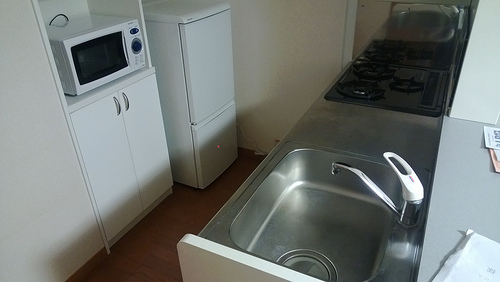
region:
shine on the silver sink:
[283, 158, 320, 189]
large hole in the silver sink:
[287, 243, 352, 275]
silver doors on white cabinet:
[95, 88, 143, 120]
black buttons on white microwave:
[113, 20, 153, 74]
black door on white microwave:
[62, 35, 150, 84]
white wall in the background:
[243, 24, 318, 91]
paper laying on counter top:
[468, 122, 497, 164]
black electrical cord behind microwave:
[47, 12, 96, 37]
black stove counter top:
[328, 37, 453, 112]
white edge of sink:
[165, 202, 260, 265]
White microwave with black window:
[46, 18, 169, 90]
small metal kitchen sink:
[260, 128, 415, 280]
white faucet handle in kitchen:
[367, 144, 425, 218]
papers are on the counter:
[481, 116, 499, 169]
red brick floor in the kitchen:
[133, 162, 200, 279]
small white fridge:
[161, 3, 262, 205]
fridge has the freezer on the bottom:
[187, 98, 244, 200]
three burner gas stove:
[338, 60, 439, 111]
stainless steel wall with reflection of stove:
[352, 0, 468, 71]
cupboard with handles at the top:
[63, 80, 181, 212]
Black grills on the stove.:
[336, 35, 428, 109]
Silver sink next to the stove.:
[241, 142, 385, 279]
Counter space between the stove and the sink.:
[319, 92, 443, 164]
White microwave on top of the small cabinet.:
[47, 28, 159, 81]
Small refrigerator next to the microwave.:
[150, 10, 250, 192]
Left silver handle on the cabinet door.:
[112, 96, 125, 116]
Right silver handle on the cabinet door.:
[122, 94, 135, 106]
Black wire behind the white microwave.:
[44, 12, 79, 23]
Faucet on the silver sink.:
[329, 149, 396, 215]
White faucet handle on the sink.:
[380, 141, 428, 198]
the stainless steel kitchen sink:
[226, 142, 402, 279]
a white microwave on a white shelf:
[41, 8, 153, 98]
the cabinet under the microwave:
[58, 89, 175, 246]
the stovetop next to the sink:
[326, 59, 448, 125]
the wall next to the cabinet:
[233, 2, 341, 152]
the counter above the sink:
[416, 111, 498, 279]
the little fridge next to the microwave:
[148, 5, 241, 191]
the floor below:
[58, 131, 273, 277]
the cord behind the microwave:
[51, 12, 73, 24]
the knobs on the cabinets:
[101, 87, 136, 113]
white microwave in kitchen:
[38, 3, 172, 106]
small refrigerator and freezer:
[143, 2, 300, 200]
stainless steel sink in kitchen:
[196, 70, 423, 273]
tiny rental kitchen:
[5, 2, 428, 278]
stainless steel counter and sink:
[261, 54, 386, 280]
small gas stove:
[346, 22, 446, 132]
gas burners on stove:
[335, 31, 448, 132]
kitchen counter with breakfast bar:
[267, 63, 498, 264]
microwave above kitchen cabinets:
[43, 16, 188, 255]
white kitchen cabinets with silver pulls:
[63, 70, 190, 265]